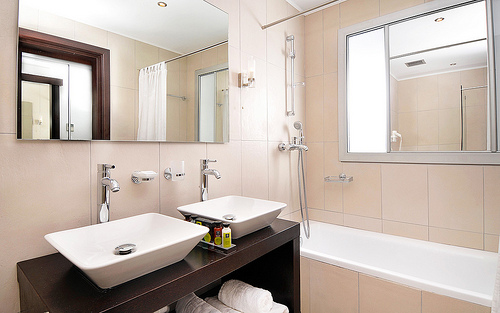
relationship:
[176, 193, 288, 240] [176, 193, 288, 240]
sink on sink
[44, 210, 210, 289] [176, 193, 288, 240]
sink on sink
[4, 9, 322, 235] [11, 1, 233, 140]
wall has mirror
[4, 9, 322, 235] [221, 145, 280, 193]
wall has tile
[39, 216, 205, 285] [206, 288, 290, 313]
sink in front of towels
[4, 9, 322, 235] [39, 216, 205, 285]
wall over sink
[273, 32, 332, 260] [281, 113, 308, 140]
shower has head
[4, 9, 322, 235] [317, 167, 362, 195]
wall has grab bar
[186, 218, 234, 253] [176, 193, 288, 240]
toiletries are between sink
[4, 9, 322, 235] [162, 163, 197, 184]
wall has cup holder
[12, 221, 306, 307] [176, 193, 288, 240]
vanity has sink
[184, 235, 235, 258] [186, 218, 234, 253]
tray has toiletries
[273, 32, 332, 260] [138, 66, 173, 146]
shower has curtain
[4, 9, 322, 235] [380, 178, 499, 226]
wall has tiles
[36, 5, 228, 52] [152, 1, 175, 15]
ceiling has light fixture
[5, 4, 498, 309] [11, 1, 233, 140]
bathroom has mirror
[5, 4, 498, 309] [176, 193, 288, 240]
bathroom has sink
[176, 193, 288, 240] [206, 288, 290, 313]
sink are above towels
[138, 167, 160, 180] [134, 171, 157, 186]
soap has dish